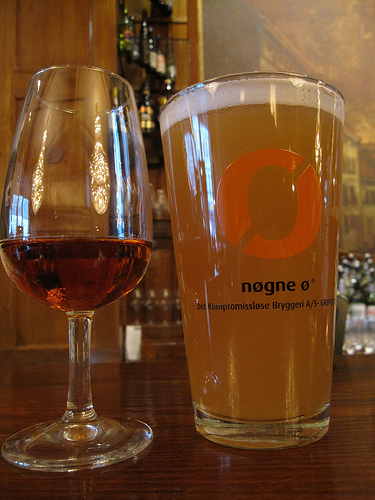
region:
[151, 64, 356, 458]
tall glass of yellow beverage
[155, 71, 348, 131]
white froth on top of yellow beverage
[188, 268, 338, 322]
black words on front of glass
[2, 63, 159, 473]
wine glass with red liquid in it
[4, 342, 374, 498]
brown wooden bar counter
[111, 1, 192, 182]
shelves of wine bottles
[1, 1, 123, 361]
side of wooden shelving unit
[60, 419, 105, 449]
light reflected on bottom of wine glass stem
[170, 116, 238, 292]
reflection of windows in sides of glass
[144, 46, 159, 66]
white label on front of wine bottle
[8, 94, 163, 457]
small and round champagne glass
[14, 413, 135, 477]
round base on glass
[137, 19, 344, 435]
tall glass with beer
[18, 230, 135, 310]
brown liquor in glass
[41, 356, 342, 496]
glasses on wood table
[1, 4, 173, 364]
brown door behind glasses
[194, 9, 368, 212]
picture on wall behind glasses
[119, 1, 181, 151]
bottles next to door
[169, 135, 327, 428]
orange beer in glass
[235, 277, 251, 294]
Black letter etched onto glass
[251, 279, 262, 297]
Black letter etched onto glass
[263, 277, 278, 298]
Black letter etched onto glass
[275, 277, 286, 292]
Black letter etched onto glass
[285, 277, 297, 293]
Black letter etched onto glass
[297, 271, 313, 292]
Black letter etched onto glass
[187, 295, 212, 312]
Black letter etched onto glass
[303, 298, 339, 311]
Black letter etched onto glass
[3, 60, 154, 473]
this is a glass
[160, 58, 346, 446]
this is a glass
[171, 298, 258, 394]
this wine in a glad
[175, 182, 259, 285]
this wine in a glad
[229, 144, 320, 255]
this wine in a glad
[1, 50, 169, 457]
wine in a glass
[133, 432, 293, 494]
the table is brown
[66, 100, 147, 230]
the glass is reflecting the light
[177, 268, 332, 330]
black writing on the glass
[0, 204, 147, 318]
the liquid is amber colored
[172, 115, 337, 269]
an o on the glass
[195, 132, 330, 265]
the o is orange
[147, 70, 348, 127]
foam at the top of the drink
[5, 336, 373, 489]
The wooden table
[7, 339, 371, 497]
A wooden table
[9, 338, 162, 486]
The bottom of the glass to the left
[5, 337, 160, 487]
A bottom of the glass to the left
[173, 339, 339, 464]
The bottom of the glass to the right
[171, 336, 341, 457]
A bottom of the glass to the right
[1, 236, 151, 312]
The wine in the glass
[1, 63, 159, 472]
The wineglass on the table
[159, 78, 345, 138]
The foam in the beer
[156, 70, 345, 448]
The glass with the beer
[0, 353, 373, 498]
The table under the glasses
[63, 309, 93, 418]
The stem of the glass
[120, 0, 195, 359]
The cabinet behind the glasses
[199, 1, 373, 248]
The wall is painted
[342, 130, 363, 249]
The white building painted on the wall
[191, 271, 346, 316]
black writing on tall mug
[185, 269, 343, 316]
black writing on tall mug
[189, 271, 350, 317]
black writing on tall mug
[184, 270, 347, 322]
black writing on tall mug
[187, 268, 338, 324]
black writing on tall mug